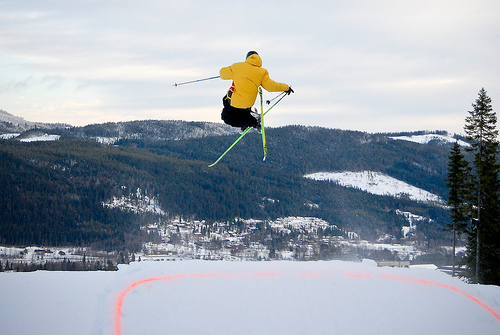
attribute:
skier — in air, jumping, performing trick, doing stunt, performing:
[218, 43, 290, 181]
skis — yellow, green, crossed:
[205, 88, 292, 172]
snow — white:
[93, 248, 425, 333]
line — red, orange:
[118, 267, 500, 332]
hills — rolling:
[9, 128, 496, 239]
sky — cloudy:
[3, 14, 173, 117]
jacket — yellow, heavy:
[216, 56, 291, 108]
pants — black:
[205, 89, 253, 127]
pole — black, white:
[173, 66, 238, 92]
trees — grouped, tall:
[446, 98, 495, 286]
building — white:
[408, 258, 438, 271]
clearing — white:
[317, 158, 425, 203]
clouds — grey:
[290, 8, 499, 94]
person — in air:
[187, 36, 292, 167]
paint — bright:
[111, 264, 494, 330]